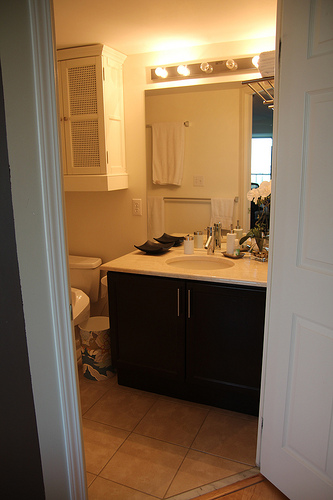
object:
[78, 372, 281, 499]
floor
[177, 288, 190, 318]
handles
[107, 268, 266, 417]
cabinet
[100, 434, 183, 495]
tile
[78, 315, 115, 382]
trashcan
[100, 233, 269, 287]
countertop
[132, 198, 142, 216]
outlet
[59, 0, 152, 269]
wall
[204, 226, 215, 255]
faucet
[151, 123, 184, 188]
towel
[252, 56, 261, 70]
light bulb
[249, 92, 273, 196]
mirror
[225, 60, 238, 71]
light bulb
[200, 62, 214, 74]
light bulb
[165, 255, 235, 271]
sink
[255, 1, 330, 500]
doorframe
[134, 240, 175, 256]
dish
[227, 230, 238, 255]
dispenser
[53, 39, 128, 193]
cabinet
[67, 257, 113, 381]
toilet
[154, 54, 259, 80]
light fixture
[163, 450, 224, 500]
groutline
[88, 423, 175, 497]
groutline